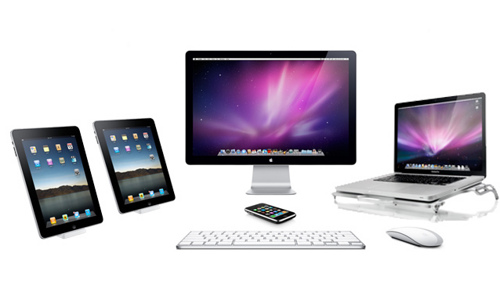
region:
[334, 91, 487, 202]
an Apple MacBook laptop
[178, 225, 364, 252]
an Apple wireless keyboard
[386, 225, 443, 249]
an Apple Magic mouse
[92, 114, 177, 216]
an Apple iPad tablet computer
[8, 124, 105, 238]
an Apple iPad tablet computer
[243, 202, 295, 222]
a black Apple iPhone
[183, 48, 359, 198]
an Apple Cinema display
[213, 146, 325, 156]
Apple Mac OS X dock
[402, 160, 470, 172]
Apple Mac OS X dock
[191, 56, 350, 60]
Apple Mac OS menu bar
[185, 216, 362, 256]
white wireless keyboard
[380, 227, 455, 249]
white wireless computer mouse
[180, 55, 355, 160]
computer with purple screen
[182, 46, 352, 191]
iMac with purple screen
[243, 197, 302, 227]
cell phone next to keyboard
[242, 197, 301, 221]
cell phone next moniter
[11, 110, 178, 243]
2 tablets in a row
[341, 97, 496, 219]
laptop on a stand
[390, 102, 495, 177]
lap top has purple screen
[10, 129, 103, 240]
tablet has picture of a moutain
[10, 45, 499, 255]
a set of electronic computing device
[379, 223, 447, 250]
a white mouse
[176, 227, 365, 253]
a thin white keyboard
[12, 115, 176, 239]
a pair of tablets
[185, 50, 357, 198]
a flat screen computer moniter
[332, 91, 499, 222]
a light colored laptop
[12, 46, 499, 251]
a display of Apple products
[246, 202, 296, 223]
a smartphone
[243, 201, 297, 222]
a Apple smartphone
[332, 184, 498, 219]
an Apple brand laptop stand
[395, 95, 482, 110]
Apple Mac OS menu bar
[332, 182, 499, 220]
a clear plastic laptop stand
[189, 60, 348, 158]
Mac OS Snow Leopard wallpaper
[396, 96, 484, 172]
Mac OS Snow Leopard wallpaper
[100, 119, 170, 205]
Apple iOS operating system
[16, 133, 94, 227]
Apple iOS operating system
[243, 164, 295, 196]
brushed aluminum monitor stand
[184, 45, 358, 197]
a computer monitor display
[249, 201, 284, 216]
Apple iOS operating system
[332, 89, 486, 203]
an open laptop computer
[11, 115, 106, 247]
electronic device on display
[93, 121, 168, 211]
electronic device on display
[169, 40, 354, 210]
electronic device on display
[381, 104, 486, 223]
electronic device on display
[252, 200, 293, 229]
electronic device on display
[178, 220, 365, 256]
electronic device on display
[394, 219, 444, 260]
electronic device on display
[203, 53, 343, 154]
screen on the computer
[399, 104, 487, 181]
screen on the computer